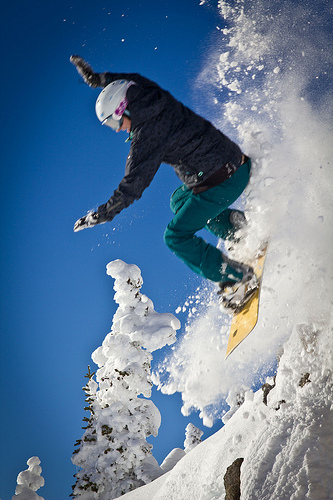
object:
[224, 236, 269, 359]
snow board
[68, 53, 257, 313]
man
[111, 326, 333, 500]
hill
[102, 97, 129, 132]
goggles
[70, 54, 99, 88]
gloves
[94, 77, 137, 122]
helmet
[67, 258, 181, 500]
pine tree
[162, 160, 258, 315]
pants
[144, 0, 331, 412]
snow powder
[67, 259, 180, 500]
tree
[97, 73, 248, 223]
jacket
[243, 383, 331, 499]
snow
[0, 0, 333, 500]
picture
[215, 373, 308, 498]
ground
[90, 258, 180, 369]
snow